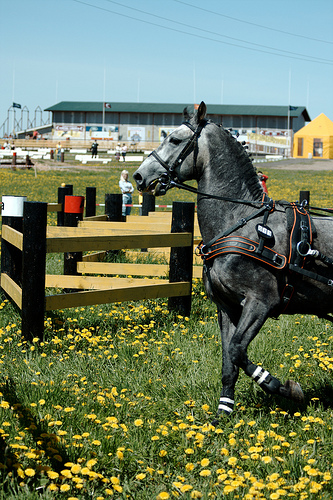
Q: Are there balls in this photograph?
A: No, there are no balls.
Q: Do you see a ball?
A: No, there are no balls.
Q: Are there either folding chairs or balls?
A: No, there are no balls or folding chairs.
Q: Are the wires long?
A: Yes, the wires are long.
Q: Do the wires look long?
A: Yes, the wires are long.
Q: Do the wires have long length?
A: Yes, the wires are long.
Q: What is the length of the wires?
A: The wires are long.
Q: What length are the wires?
A: The wires are long.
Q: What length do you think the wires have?
A: The wires have long length.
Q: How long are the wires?
A: The wires are long.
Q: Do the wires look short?
A: No, the wires are long.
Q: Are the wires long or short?
A: The wires are long.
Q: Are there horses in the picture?
A: Yes, there is a horse.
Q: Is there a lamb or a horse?
A: Yes, there is a horse.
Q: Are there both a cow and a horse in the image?
A: No, there is a horse but no cows.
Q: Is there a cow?
A: No, there are no cows.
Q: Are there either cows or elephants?
A: No, there are no cows or elephants.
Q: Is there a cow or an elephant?
A: No, there are no cows or elephants.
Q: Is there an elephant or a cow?
A: No, there are no cows or elephants.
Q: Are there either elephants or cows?
A: No, there are no cows or elephants.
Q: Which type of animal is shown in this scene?
A: The animal is a horse.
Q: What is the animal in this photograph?
A: The animal is a horse.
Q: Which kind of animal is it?
A: The animal is a horse.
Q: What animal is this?
A: This is a horse.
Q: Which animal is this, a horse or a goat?
A: This is a horse.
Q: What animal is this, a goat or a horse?
A: This is a horse.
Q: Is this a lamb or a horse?
A: This is a horse.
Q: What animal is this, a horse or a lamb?
A: This is a horse.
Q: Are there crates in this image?
A: No, there are no crates.